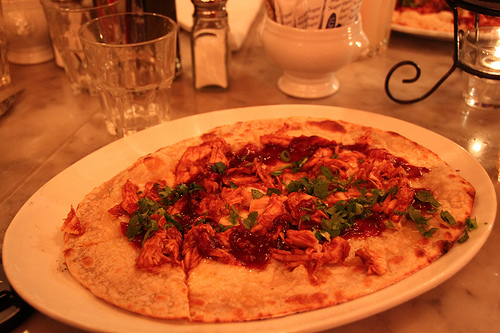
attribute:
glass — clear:
[39, 1, 132, 101]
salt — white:
[184, 0, 237, 93]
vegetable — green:
[439, 206, 460, 229]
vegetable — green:
[278, 149, 294, 163]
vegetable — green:
[249, 185, 266, 201]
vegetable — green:
[411, 188, 443, 212]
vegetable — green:
[456, 230, 471, 243]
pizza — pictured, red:
[49, 96, 471, 331]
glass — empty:
[72, 15, 181, 132]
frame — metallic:
[383, 47, 457, 111]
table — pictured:
[4, 101, 84, 170]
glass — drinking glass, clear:
[77, 9, 178, 143]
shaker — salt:
[189, 0, 231, 95]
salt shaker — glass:
[187, 3, 238, 101]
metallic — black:
[384, 3, 496, 101]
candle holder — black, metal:
[384, 0, 492, 105]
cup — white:
[260, 16, 367, 100]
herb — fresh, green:
[317, 197, 382, 244]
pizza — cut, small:
[61, 112, 476, 330]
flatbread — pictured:
[33, 103, 479, 309]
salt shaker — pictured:
[178, 35, 266, 124]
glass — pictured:
[83, 11, 180, 133]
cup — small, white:
[2, 0, 54, 64]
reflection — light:
[460, 122, 494, 157]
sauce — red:
[171, 132, 388, 272]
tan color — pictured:
[63, 233, 127, 305]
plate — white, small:
[0, 104, 495, 331]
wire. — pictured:
[363, 17, 475, 114]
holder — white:
[259, 18, 364, 101]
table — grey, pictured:
[0, 42, 497, 331]